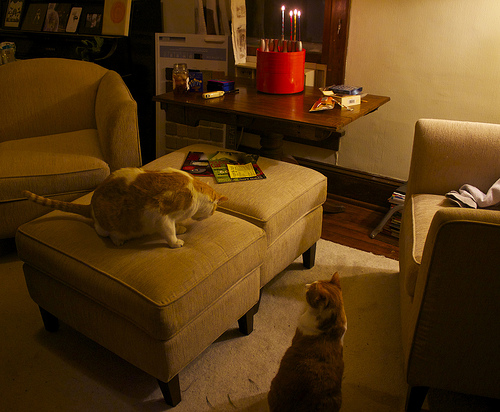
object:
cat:
[20, 162, 219, 249]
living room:
[0, 0, 499, 410]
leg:
[153, 377, 181, 405]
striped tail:
[16, 184, 96, 220]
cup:
[256, 39, 302, 94]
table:
[159, 68, 386, 155]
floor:
[2, 147, 410, 410]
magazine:
[204, 146, 267, 181]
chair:
[134, 136, 326, 293]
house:
[4, 0, 500, 412]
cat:
[262, 266, 344, 411]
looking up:
[260, 265, 354, 406]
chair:
[13, 178, 275, 405]